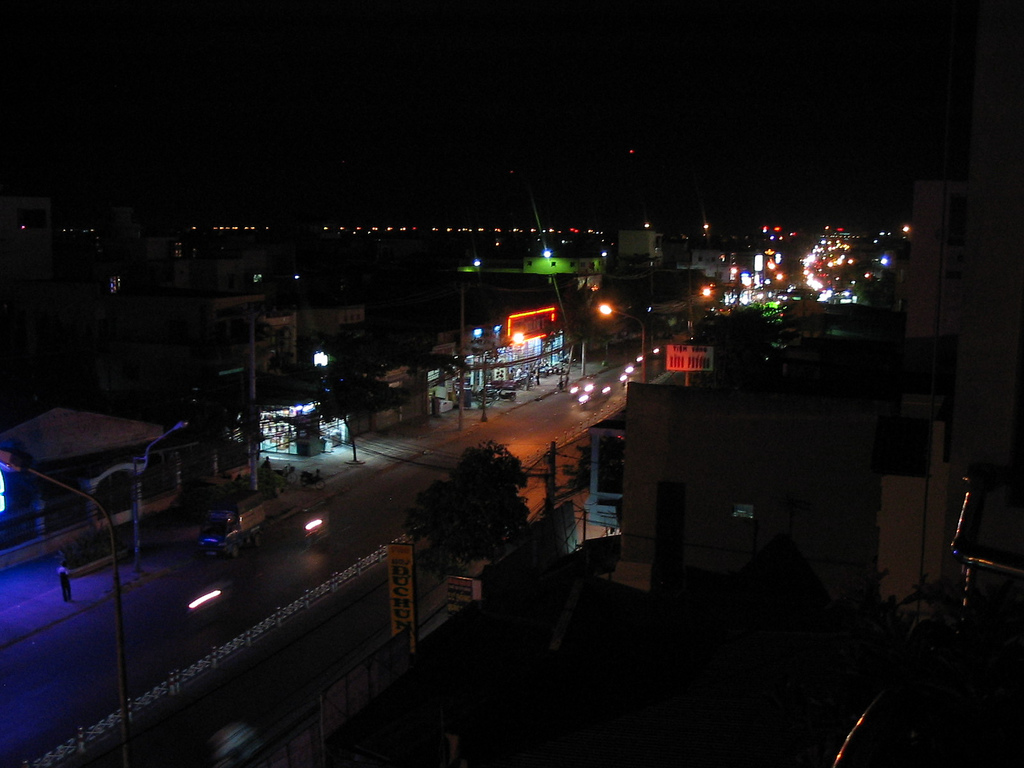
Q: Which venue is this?
A: This is a road.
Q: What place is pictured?
A: It is a road.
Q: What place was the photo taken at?
A: It was taken at the road.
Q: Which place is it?
A: It is a road.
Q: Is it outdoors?
A: Yes, it is outdoors.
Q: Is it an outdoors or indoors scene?
A: It is outdoors.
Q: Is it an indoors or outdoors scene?
A: It is outdoors.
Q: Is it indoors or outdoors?
A: It is outdoors.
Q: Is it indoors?
A: No, it is outdoors.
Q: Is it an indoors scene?
A: No, it is outdoors.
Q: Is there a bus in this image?
A: No, there are no buses.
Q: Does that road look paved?
A: Yes, the road is paved.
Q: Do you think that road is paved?
A: Yes, the road is paved.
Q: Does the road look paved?
A: Yes, the road is paved.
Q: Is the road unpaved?
A: No, the road is paved.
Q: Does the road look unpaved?
A: No, the road is paved.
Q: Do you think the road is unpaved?
A: No, the road is paved.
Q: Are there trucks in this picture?
A: Yes, there is a truck.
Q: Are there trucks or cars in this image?
A: Yes, there is a truck.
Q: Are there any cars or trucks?
A: Yes, there is a truck.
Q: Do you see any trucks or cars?
A: Yes, there is a truck.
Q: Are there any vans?
A: No, there are no vans.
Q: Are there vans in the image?
A: No, there are no vans.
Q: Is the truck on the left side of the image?
A: Yes, the truck is on the left of the image.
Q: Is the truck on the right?
A: No, the truck is on the left of the image.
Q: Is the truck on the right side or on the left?
A: The truck is on the left of the image.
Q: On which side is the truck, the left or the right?
A: The truck is on the left of the image.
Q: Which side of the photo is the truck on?
A: The truck is on the left of the image.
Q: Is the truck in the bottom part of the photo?
A: Yes, the truck is in the bottom of the image.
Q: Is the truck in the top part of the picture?
A: No, the truck is in the bottom of the image.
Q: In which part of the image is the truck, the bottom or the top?
A: The truck is in the bottom of the image.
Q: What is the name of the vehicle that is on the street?
A: The vehicle is a truck.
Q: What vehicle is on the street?
A: The vehicle is a truck.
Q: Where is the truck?
A: The truck is on the street.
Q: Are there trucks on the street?
A: Yes, there is a truck on the street.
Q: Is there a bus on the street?
A: No, there is a truck on the street.